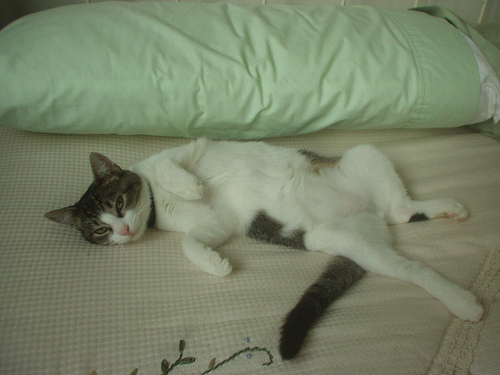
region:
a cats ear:
[91, 150, 119, 185]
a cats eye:
[111, 191, 127, 216]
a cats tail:
[268, 290, 341, 364]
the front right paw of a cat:
[181, 235, 227, 284]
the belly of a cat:
[226, 165, 296, 217]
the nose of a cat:
[114, 217, 136, 237]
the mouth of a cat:
[125, 213, 141, 248]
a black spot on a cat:
[402, 205, 429, 234]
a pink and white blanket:
[39, 304, 136, 372]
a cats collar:
[141, 170, 155, 239]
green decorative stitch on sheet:
[182, 335, 258, 368]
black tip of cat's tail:
[275, 304, 317, 374]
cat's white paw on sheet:
[176, 239, 252, 296]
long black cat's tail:
[259, 254, 409, 364]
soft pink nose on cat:
[113, 222, 143, 249]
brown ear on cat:
[81, 141, 141, 195]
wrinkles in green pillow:
[162, 79, 279, 124]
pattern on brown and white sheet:
[50, 287, 152, 333]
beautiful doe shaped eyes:
[87, 179, 164, 253]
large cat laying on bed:
[32, 142, 480, 353]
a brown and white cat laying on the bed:
[38, 138, 479, 363]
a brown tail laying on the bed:
[282, 249, 357, 355]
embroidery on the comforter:
[154, 332, 281, 372]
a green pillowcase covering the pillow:
[8, 6, 483, 133]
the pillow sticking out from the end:
[460, 38, 499, 130]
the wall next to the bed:
[412, 1, 495, 28]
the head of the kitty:
[48, 156, 148, 251]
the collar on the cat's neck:
[133, 174, 160, 238]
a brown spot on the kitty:
[251, 205, 302, 252]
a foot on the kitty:
[386, 197, 471, 228]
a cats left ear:
[89, 150, 111, 180]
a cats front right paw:
[181, 229, 221, 286]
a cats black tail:
[267, 276, 349, 366]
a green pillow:
[28, 64, 397, 134]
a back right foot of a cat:
[397, 257, 492, 332]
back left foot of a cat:
[401, 167, 471, 229]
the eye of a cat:
[111, 190, 128, 216]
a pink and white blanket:
[44, 289, 243, 346]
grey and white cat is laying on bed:
[11, 133, 461, 326]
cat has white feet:
[161, 153, 237, 288]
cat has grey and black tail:
[245, 227, 388, 357]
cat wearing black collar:
[137, 182, 172, 249]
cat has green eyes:
[52, 160, 157, 280]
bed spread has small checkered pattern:
[48, 274, 272, 327]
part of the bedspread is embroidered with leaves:
[110, 329, 270, 372]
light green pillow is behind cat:
[55, 36, 479, 172]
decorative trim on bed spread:
[410, 318, 485, 373]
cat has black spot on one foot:
[400, 182, 463, 242]